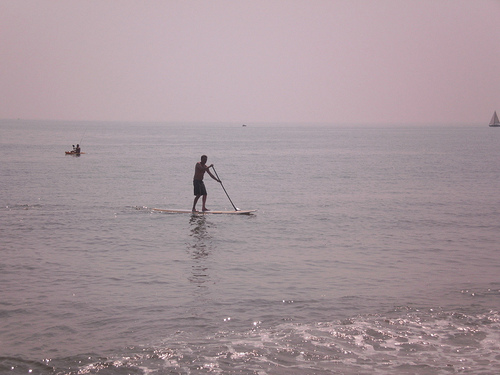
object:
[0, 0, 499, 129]
sky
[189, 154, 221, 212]
man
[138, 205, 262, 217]
surfboard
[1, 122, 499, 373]
water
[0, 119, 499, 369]
ocean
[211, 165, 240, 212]
paddle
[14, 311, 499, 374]
ripple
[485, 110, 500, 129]
boat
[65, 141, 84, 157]
people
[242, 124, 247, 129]
object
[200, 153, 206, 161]
hair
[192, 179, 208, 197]
shorts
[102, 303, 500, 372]
wave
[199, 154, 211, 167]
head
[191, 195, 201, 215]
legs